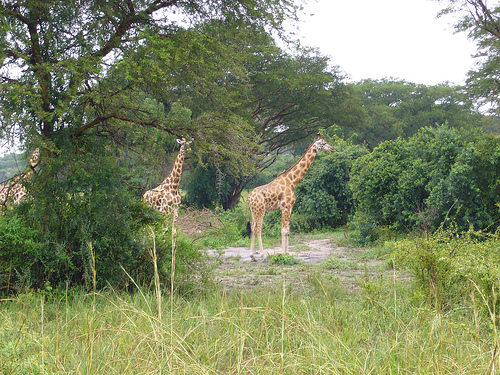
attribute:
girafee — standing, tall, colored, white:
[239, 133, 338, 271]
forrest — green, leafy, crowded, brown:
[16, 29, 482, 293]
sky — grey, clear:
[343, 3, 409, 44]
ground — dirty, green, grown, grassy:
[231, 252, 287, 283]